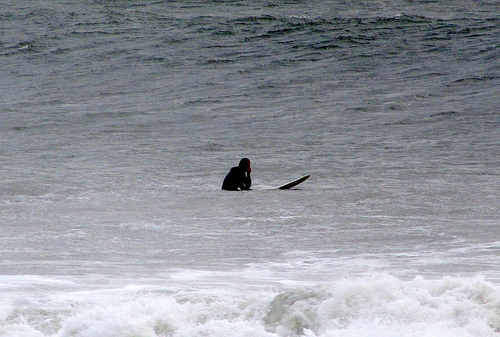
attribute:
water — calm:
[85, 214, 212, 284]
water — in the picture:
[1, 0, 499, 281]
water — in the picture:
[126, 67, 179, 130]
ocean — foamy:
[28, 33, 488, 335]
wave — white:
[93, 259, 475, 335]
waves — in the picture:
[224, 195, 391, 331]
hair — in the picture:
[239, 157, 247, 164]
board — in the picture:
[272, 172, 311, 187]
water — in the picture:
[248, 215, 497, 262]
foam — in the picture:
[254, 181, 274, 196]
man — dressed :
[181, 116, 260, 222]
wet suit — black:
[219, 154, 258, 190]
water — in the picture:
[273, 252, 410, 322]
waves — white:
[0, 270, 497, 334]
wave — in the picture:
[258, 7, 493, 116]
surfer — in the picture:
[213, 147, 259, 194]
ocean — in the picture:
[2, 1, 499, 333]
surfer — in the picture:
[217, 154, 257, 191]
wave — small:
[232, 10, 497, 73]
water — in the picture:
[1, 3, 498, 334]